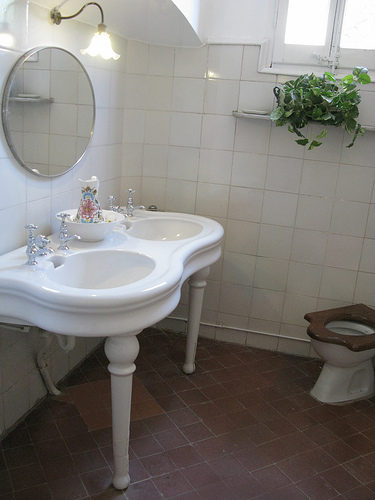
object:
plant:
[272, 65, 370, 151]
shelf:
[233, 105, 375, 132]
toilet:
[303, 303, 374, 406]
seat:
[303, 303, 374, 352]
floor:
[4, 328, 370, 499]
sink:
[0, 206, 225, 494]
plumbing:
[36, 334, 62, 398]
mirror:
[3, 45, 97, 180]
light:
[50, 2, 122, 61]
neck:
[60, 2, 106, 32]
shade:
[79, 31, 121, 61]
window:
[279, 1, 375, 66]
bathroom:
[2, 2, 373, 499]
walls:
[5, 4, 374, 358]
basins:
[1, 245, 178, 337]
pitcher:
[73, 175, 105, 223]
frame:
[0, 43, 98, 180]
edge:
[80, 49, 121, 61]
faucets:
[56, 211, 82, 251]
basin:
[57, 209, 123, 243]